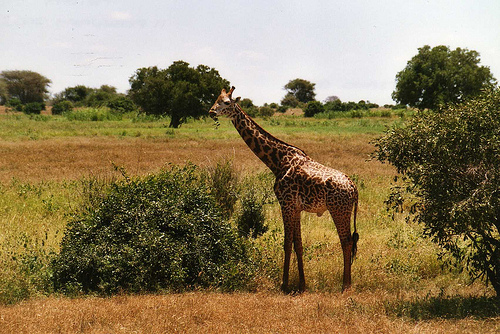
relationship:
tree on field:
[126, 59, 229, 131] [18, 110, 241, 159]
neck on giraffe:
[227, 104, 286, 175] [208, 85, 358, 292]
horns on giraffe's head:
[216, 83, 237, 100] [200, 83, 241, 123]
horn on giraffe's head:
[228, 85, 235, 95] [208, 86, 243, 119]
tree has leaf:
[126, 59, 231, 131] [149, 76, 166, 85]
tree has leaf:
[126, 59, 231, 131] [181, 90, 196, 102]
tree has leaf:
[126, 59, 231, 131] [173, 75, 190, 85]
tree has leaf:
[126, 59, 231, 131] [145, 100, 160, 115]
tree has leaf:
[126, 59, 231, 131] [176, 63, 184, 72]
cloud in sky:
[105, 6, 142, 28] [2, 3, 499, 109]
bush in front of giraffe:
[81, 171, 216, 292] [215, 73, 432, 304]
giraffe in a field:
[208, 85, 358, 292] [6, 102, 496, 332]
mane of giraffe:
[247, 112, 309, 154] [195, 81, 392, 301]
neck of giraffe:
[232, 105, 283, 175] [208, 85, 358, 292]